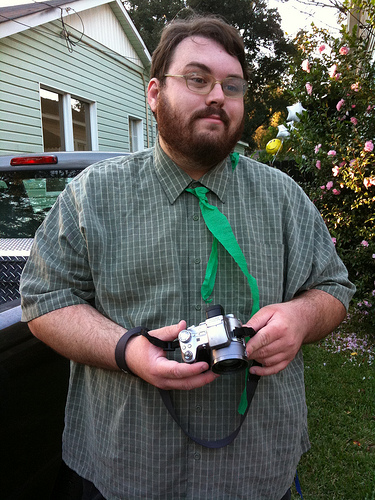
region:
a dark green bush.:
[314, 389, 374, 497]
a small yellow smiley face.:
[262, 137, 283, 153]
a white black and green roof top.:
[0, 0, 152, 80]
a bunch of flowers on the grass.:
[328, 333, 374, 363]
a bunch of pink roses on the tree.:
[313, 29, 374, 235]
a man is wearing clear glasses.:
[159, 66, 250, 101]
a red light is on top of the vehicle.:
[6, 151, 60, 167]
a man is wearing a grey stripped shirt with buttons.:
[144, 210, 202, 295]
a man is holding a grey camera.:
[173, 302, 254, 372]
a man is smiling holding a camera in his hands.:
[16, 13, 358, 498]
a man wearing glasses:
[93, 16, 260, 146]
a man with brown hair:
[157, 13, 284, 198]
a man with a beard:
[121, 24, 325, 202]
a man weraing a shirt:
[115, 31, 374, 425]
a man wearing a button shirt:
[37, 48, 347, 484]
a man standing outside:
[78, 46, 334, 493]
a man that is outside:
[46, 34, 365, 400]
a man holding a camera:
[69, 217, 329, 491]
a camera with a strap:
[52, 265, 316, 498]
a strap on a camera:
[121, 287, 329, 488]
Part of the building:
[20, 55, 75, 69]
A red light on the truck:
[9, 153, 59, 168]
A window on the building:
[36, 79, 70, 155]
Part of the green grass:
[322, 400, 333, 460]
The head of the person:
[144, 3, 252, 173]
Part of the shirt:
[107, 235, 138, 275]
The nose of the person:
[204, 75, 227, 110]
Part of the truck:
[7, 329, 23, 371]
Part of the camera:
[200, 323, 225, 348]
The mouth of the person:
[194, 110, 226, 123]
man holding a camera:
[19, 12, 357, 495]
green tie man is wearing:
[189, 185, 262, 320]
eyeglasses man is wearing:
[161, 66, 252, 102]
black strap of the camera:
[133, 324, 180, 362]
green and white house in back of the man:
[2, 2, 161, 195]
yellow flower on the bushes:
[262, 135, 285, 158]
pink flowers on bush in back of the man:
[303, 33, 371, 198]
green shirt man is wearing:
[19, 138, 355, 496]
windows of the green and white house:
[36, 82, 101, 155]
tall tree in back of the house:
[126, 3, 312, 146]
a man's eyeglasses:
[155, 68, 253, 99]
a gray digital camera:
[171, 312, 251, 368]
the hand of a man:
[240, 301, 304, 378]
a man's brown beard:
[155, 91, 246, 164]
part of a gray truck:
[1, 152, 145, 403]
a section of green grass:
[295, 362, 374, 497]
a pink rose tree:
[282, 23, 373, 288]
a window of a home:
[41, 83, 67, 149]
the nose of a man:
[201, 78, 225, 104]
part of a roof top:
[0, 0, 71, 26]